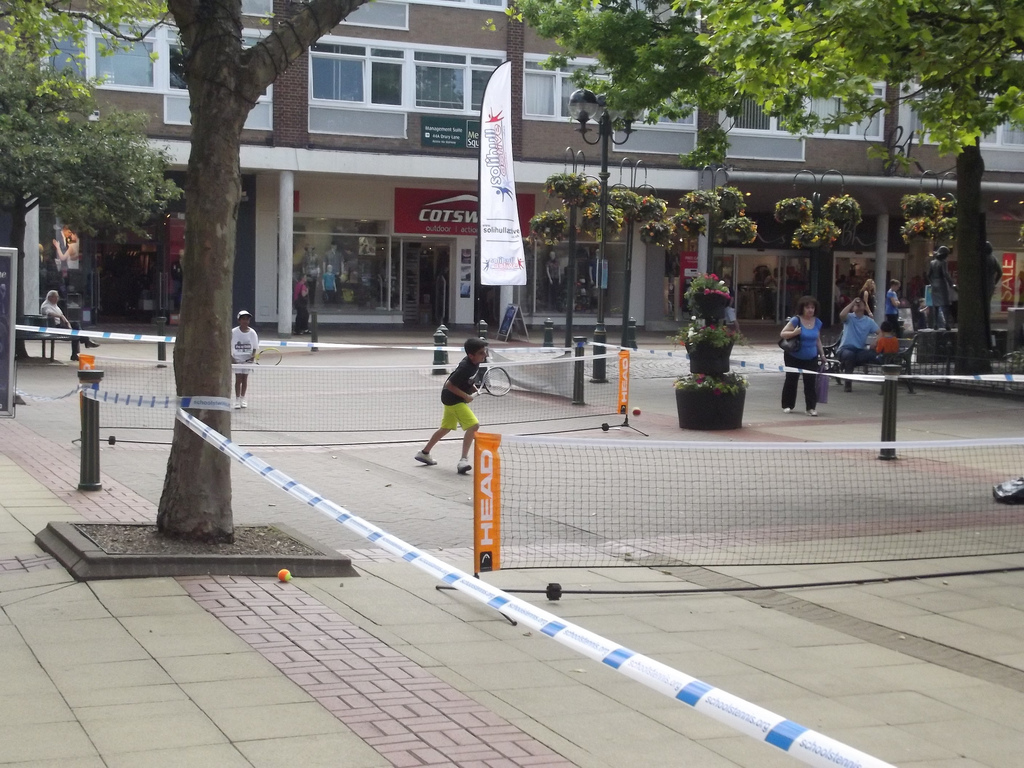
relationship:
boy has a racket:
[413, 334, 512, 485] [472, 367, 518, 404]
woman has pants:
[780, 291, 833, 420] [785, 354, 821, 412]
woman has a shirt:
[780, 291, 833, 420] [785, 315, 828, 361]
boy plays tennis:
[413, 334, 512, 485] [161, 320, 1022, 616]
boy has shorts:
[413, 334, 512, 485] [445, 398, 479, 438]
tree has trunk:
[17, 4, 375, 548] [154, 119, 242, 551]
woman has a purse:
[780, 291, 833, 420] [780, 317, 804, 353]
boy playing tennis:
[413, 334, 512, 485] [161, 320, 1022, 616]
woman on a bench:
[43, 281, 100, 365] [16, 314, 76, 369]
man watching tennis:
[837, 297, 880, 390] [161, 320, 1022, 616]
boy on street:
[413, 336, 492, 475] [5, 322, 1022, 766]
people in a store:
[305, 244, 817, 336] [298, 155, 1023, 338]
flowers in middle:
[678, 275, 754, 434] [558, 323, 885, 472]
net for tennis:
[20, 316, 662, 437] [161, 320, 1022, 616]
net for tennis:
[470, 421, 1022, 589] [161, 320, 1022, 616]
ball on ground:
[279, 565, 297, 587] [5, 322, 1022, 766]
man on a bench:
[837, 297, 880, 390] [823, 332, 928, 389]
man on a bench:
[43, 281, 100, 365] [16, 314, 76, 369]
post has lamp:
[592, 114, 625, 386] [567, 86, 651, 133]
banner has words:
[477, 58, 539, 291] [482, 113, 520, 280]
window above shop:
[312, 39, 371, 112] [4, 3, 1023, 349]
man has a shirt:
[837, 297, 880, 390] [843, 310, 886, 354]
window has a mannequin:
[283, 216, 633, 325] [306, 245, 342, 305]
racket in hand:
[472, 367, 518, 404] [461, 381, 491, 407]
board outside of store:
[494, 300, 532, 345] [298, 155, 1023, 338]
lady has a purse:
[780, 291, 833, 420] [780, 317, 804, 353]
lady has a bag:
[780, 291, 833, 420] [812, 348, 845, 414]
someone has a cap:
[227, 310, 265, 411] [236, 310, 253, 321]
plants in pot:
[678, 275, 754, 434] [677, 325, 749, 423]